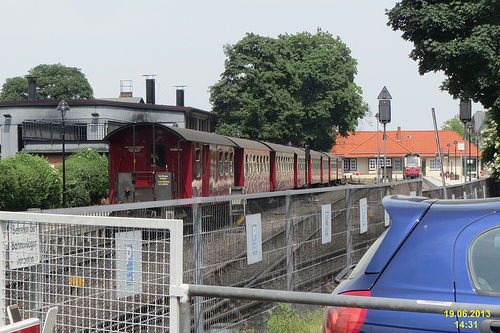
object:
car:
[323, 195, 498, 333]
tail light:
[322, 290, 369, 332]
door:
[452, 209, 498, 332]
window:
[466, 227, 499, 295]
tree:
[210, 0, 499, 180]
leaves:
[207, 0, 500, 182]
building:
[330, 130, 482, 176]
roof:
[329, 130, 481, 158]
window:
[194, 149, 338, 179]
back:
[106, 122, 190, 224]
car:
[102, 122, 346, 205]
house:
[0, 97, 215, 170]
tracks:
[28, 223, 322, 294]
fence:
[0, 199, 183, 333]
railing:
[187, 285, 500, 318]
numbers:
[444, 310, 491, 329]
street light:
[56, 100, 71, 206]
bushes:
[0, 147, 109, 212]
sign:
[115, 230, 142, 298]